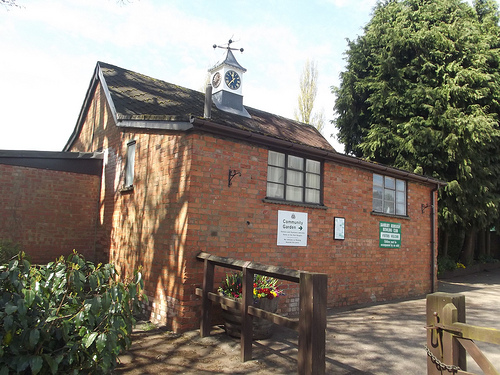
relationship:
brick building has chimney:
[0, 27, 447, 336] [195, 82, 215, 122]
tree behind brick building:
[329, 0, 499, 276] [0, 27, 447, 336]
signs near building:
[276, 209, 308, 246] [193, 183, 430, 293]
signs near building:
[333, 216, 345, 239] [193, 183, 430, 293]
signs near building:
[378, 220, 400, 250] [193, 183, 430, 293]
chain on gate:
[422, 348, 457, 373] [425, 288, 499, 374]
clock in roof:
[206, 66, 246, 93] [58, 57, 448, 183]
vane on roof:
[208, 30, 253, 59] [58, 57, 450, 184]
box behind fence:
[206, 265, 299, 346] [192, 247, 327, 370]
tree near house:
[334, 2, 497, 277] [7, 41, 434, 294]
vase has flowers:
[258, 294, 275, 305] [259, 276, 282, 299]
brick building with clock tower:
[1, 27, 453, 339] [202, 29, 256, 122]